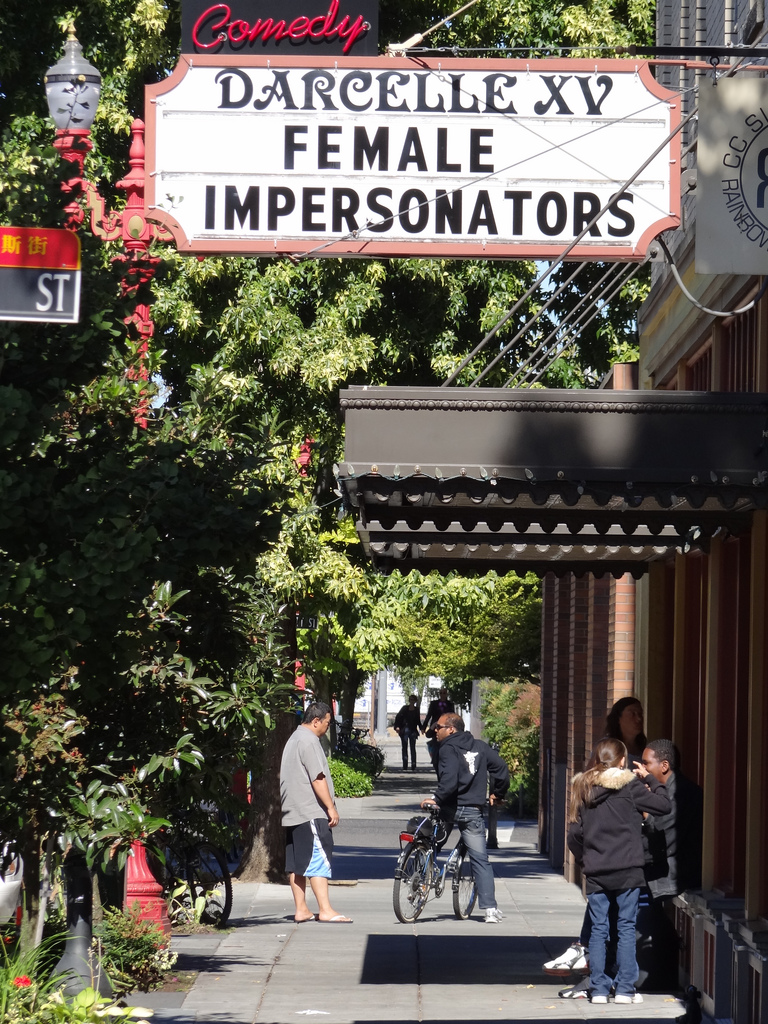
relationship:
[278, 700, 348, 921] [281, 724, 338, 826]
man wearing shirt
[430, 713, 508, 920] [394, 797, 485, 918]
man holding bicycle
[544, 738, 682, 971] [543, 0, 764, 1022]
man leaning on side of building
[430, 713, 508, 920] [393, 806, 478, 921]
man standing with h bike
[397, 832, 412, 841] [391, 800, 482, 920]
reflector light on back of bike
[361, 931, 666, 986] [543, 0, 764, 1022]
shadow of building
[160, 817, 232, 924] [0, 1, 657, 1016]
bicycle parked under tree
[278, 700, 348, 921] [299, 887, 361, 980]
man wearing shorts and flip flops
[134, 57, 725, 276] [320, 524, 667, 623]
sign with black letters